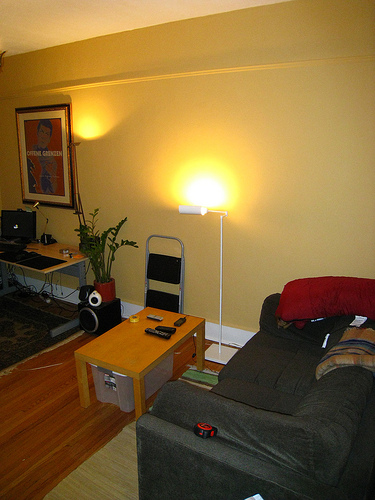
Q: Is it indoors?
A: Yes, it is indoors.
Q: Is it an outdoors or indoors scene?
A: It is indoors.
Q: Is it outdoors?
A: No, it is indoors.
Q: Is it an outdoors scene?
A: No, it is indoors.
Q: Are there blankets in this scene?
A: Yes, there is a blanket.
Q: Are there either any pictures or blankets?
A: Yes, there is a blanket.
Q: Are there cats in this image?
A: No, there are no cats.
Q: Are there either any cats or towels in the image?
A: No, there are no cats or towels.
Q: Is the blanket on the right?
A: Yes, the blanket is on the right of the image.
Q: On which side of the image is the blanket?
A: The blanket is on the right of the image.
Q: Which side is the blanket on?
A: The blanket is on the right of the image.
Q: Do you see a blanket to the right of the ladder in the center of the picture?
A: Yes, there is a blanket to the right of the ladder.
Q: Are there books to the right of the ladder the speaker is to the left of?
A: No, there is a blanket to the right of the ladder.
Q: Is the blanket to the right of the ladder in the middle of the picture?
A: Yes, the blanket is to the right of the ladder.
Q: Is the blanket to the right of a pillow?
A: No, the blanket is to the right of the ladder.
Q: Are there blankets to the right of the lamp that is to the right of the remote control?
A: Yes, there is a blanket to the right of the lamp.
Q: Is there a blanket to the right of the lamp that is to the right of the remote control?
A: Yes, there is a blanket to the right of the lamp.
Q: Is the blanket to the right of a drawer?
A: No, the blanket is to the right of the lamp.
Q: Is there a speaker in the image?
A: Yes, there is a speaker.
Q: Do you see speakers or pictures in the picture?
A: Yes, there is a speaker.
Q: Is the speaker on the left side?
A: Yes, the speaker is on the left of the image.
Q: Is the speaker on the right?
A: No, the speaker is on the left of the image.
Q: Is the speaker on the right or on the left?
A: The speaker is on the left of the image.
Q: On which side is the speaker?
A: The speaker is on the left of the image.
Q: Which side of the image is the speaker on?
A: The speaker is on the left of the image.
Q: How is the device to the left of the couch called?
A: The device is a speaker.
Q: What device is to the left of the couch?
A: The device is a speaker.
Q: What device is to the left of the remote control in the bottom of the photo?
A: The device is a speaker.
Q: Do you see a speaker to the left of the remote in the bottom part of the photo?
A: Yes, there is a speaker to the left of the remote.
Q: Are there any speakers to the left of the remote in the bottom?
A: Yes, there is a speaker to the left of the remote.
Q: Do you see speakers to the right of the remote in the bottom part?
A: No, the speaker is to the left of the remote.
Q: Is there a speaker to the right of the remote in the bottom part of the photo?
A: No, the speaker is to the left of the remote.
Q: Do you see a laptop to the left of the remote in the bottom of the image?
A: No, there is a speaker to the left of the remote control.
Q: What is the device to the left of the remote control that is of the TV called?
A: The device is a speaker.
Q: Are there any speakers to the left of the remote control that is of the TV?
A: Yes, there is a speaker to the left of the remote control.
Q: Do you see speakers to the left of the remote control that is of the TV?
A: Yes, there is a speaker to the left of the remote control.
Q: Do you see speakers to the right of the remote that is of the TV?
A: No, the speaker is to the left of the remote control.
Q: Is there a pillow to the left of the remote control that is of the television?
A: No, there is a speaker to the left of the remote control.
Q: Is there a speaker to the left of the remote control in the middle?
A: Yes, there is a speaker to the left of the remote control.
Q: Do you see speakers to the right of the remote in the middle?
A: No, the speaker is to the left of the remote control.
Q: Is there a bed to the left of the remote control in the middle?
A: No, there is a speaker to the left of the remote.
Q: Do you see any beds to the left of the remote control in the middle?
A: No, there is a speaker to the left of the remote.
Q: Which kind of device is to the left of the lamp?
A: The device is a speaker.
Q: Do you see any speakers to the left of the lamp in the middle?
A: Yes, there is a speaker to the left of the lamp.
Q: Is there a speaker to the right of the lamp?
A: No, the speaker is to the left of the lamp.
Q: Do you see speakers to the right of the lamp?
A: No, the speaker is to the left of the lamp.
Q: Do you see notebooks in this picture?
A: No, there are no notebooks.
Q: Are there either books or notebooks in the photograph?
A: No, there are no notebooks or books.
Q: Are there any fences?
A: No, there are no fences.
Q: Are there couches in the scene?
A: Yes, there is a couch.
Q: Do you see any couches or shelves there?
A: Yes, there is a couch.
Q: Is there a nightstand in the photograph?
A: No, there are no nightstands.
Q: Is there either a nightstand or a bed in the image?
A: No, there are no nightstands or beds.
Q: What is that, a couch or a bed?
A: That is a couch.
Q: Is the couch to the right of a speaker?
A: Yes, the couch is to the right of a speaker.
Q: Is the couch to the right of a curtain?
A: No, the couch is to the right of a speaker.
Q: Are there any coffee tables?
A: Yes, there is a coffee table.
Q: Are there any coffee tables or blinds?
A: Yes, there is a coffee table.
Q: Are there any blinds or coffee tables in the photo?
A: Yes, there is a coffee table.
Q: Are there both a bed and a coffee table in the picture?
A: No, there is a coffee table but no beds.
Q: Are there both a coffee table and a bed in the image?
A: No, there is a coffee table but no beds.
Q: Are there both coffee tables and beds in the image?
A: No, there is a coffee table but no beds.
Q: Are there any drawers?
A: No, there are no drawers.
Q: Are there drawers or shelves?
A: No, there are no drawers or shelves.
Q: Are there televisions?
A: Yes, there is a television.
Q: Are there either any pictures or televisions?
A: Yes, there is a television.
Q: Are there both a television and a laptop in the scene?
A: No, there is a television but no laptops.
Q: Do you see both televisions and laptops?
A: No, there is a television but no laptops.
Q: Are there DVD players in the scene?
A: No, there are no DVD players.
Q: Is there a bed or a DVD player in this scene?
A: No, there are no DVD players or beds.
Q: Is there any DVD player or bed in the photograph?
A: No, there are no DVD players or beds.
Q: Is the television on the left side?
A: Yes, the television is on the left of the image.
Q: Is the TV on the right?
A: No, the TV is on the left of the image.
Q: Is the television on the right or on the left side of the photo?
A: The television is on the left of the image.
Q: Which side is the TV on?
A: The TV is on the left of the image.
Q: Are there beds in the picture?
A: No, there are no beds.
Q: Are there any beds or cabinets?
A: No, there are no beds or cabinets.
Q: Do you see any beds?
A: No, there are no beds.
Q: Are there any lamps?
A: Yes, there is a lamp.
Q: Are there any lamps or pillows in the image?
A: Yes, there is a lamp.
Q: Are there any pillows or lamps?
A: Yes, there is a lamp.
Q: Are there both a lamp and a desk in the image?
A: Yes, there are both a lamp and a desk.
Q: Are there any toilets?
A: No, there are no toilets.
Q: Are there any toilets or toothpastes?
A: No, there are no toilets or toothpastes.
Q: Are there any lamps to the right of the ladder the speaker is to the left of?
A: Yes, there is a lamp to the right of the ladder.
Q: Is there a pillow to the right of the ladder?
A: No, there is a lamp to the right of the ladder.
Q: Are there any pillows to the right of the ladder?
A: No, there is a lamp to the right of the ladder.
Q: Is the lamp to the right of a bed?
A: No, the lamp is to the right of the ladder.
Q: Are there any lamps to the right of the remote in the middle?
A: Yes, there is a lamp to the right of the remote.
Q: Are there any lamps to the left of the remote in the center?
A: No, the lamp is to the right of the remote.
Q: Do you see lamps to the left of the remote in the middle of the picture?
A: No, the lamp is to the right of the remote.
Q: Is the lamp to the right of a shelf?
A: No, the lamp is to the right of the remote.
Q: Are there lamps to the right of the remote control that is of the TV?
A: Yes, there is a lamp to the right of the remote.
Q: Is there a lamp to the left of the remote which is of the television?
A: No, the lamp is to the right of the remote control.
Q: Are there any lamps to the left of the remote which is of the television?
A: No, the lamp is to the right of the remote control.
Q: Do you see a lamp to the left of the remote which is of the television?
A: No, the lamp is to the right of the remote control.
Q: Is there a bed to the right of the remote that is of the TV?
A: No, there is a lamp to the right of the remote control.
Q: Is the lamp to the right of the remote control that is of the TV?
A: Yes, the lamp is to the right of the remote.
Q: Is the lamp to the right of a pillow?
A: No, the lamp is to the right of the remote.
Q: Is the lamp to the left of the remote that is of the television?
A: No, the lamp is to the right of the remote.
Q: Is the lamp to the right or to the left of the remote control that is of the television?
A: The lamp is to the right of the remote control.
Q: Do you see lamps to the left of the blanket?
A: Yes, there is a lamp to the left of the blanket.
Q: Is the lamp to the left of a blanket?
A: Yes, the lamp is to the left of a blanket.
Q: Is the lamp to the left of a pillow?
A: No, the lamp is to the left of a blanket.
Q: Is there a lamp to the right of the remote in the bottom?
A: Yes, there is a lamp to the right of the remote control.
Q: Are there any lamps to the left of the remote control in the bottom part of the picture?
A: No, the lamp is to the right of the remote.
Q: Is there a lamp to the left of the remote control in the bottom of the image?
A: No, the lamp is to the right of the remote.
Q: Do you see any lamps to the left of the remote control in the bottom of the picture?
A: No, the lamp is to the right of the remote.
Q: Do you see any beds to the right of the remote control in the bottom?
A: No, there is a lamp to the right of the remote.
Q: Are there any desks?
A: Yes, there is a desk.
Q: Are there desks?
A: Yes, there is a desk.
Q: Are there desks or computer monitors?
A: Yes, there is a desk.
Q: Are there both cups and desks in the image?
A: No, there is a desk but no cups.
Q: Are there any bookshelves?
A: No, there are no bookshelves.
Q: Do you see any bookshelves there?
A: No, there are no bookshelves.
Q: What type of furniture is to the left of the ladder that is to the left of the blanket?
A: The piece of furniture is a desk.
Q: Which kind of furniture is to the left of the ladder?
A: The piece of furniture is a desk.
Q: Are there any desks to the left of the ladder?
A: Yes, there is a desk to the left of the ladder.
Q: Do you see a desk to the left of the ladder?
A: Yes, there is a desk to the left of the ladder.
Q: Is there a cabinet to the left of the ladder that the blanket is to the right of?
A: No, there is a desk to the left of the ladder.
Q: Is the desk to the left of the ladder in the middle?
A: Yes, the desk is to the left of the ladder.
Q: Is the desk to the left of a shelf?
A: No, the desk is to the left of the ladder.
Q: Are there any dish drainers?
A: No, there are no dish drainers.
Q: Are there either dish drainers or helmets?
A: No, there are no dish drainers or helmets.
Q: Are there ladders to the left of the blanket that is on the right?
A: Yes, there is a ladder to the left of the blanket.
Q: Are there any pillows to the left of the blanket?
A: No, there is a ladder to the left of the blanket.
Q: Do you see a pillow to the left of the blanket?
A: No, there is a ladder to the left of the blanket.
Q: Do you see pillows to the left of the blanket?
A: No, there is a ladder to the left of the blanket.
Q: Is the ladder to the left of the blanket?
A: Yes, the ladder is to the left of the blanket.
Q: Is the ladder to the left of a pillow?
A: No, the ladder is to the left of the blanket.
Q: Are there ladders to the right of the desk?
A: Yes, there is a ladder to the right of the desk.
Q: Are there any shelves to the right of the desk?
A: No, there is a ladder to the right of the desk.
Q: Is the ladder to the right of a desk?
A: Yes, the ladder is to the right of a desk.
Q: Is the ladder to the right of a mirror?
A: No, the ladder is to the right of a desk.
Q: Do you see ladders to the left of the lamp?
A: Yes, there is a ladder to the left of the lamp.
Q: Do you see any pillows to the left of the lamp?
A: No, there is a ladder to the left of the lamp.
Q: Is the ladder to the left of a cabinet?
A: No, the ladder is to the left of the lamp.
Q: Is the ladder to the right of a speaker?
A: Yes, the ladder is to the right of a speaker.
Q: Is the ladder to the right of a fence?
A: No, the ladder is to the right of a speaker.